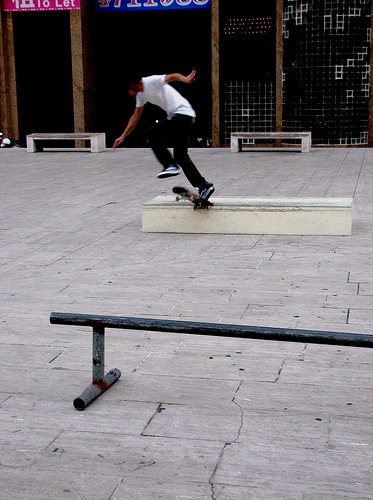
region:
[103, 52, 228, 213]
Young man skateboarding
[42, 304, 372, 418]
Skateboard trick metal rail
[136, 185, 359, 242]
Ledge for performing skatboard tricks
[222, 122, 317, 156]
Stone sitting bench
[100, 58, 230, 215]
Teenage boy in middle of performing trick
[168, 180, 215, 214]
Skateboard being used to grind ledge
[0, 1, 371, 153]
Storefronts in background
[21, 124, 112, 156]
Stone bench in front of stores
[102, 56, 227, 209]
Young man wearing white shirt and black pants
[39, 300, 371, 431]
Metal railing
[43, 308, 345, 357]
the pole is gray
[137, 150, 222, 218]
the boy is skateboarding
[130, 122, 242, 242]
the boy is skateboarding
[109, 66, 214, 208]
man on skateboard is going off a jump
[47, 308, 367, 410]
black metal pole at skate park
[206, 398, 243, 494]
cement has an uneven crack in it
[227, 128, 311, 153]
white cement bench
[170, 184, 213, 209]
black skateboard with red wheels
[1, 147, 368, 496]
skate park ground made of cement bricks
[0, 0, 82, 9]
red sign hanging on a building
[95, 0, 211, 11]
blue sign with red writing on wall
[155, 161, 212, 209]
man's front foot is off skateboard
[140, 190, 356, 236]
white rectangular platform on the ground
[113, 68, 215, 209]
A skateboarder doing a trick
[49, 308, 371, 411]
A long metal pole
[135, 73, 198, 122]
A white tee shirt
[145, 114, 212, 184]
A pair of black pants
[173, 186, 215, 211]
A black skateboard with red wheels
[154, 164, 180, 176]
A black and white gym shoe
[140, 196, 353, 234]
A concrete platform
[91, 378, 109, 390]
Red paint on metal pole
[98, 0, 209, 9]
A blue sign with red words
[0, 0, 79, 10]
A pink sign with white words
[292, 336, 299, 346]
part of a rail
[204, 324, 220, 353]
edge of a rail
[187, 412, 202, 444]
part of the ground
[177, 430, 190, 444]
side of a ground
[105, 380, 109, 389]
edge of a rail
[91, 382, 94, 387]
edge of a rail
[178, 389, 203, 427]
part of the ground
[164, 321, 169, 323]
part of a post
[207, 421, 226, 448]
part of a court